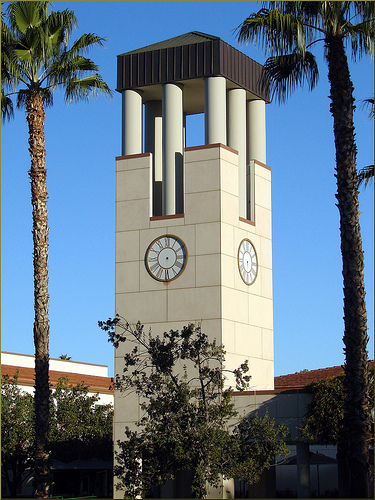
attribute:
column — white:
[163, 84, 185, 215]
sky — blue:
[72, 0, 271, 64]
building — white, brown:
[0, 352, 120, 404]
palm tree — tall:
[248, 5, 370, 101]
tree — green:
[96, 304, 278, 490]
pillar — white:
[144, 76, 215, 263]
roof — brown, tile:
[105, 16, 297, 112]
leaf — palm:
[235, 19, 335, 154]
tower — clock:
[101, 16, 283, 449]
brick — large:
[164, 282, 223, 318]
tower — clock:
[109, 11, 276, 445]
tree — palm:
[5, 0, 123, 491]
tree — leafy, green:
[101, 315, 283, 498]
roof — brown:
[98, 12, 302, 121]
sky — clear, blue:
[54, 117, 99, 229]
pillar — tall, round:
[138, 86, 193, 217]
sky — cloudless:
[29, 107, 106, 236]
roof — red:
[281, 356, 358, 396]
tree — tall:
[238, 1, 363, 291]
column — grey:
[148, 77, 206, 218]